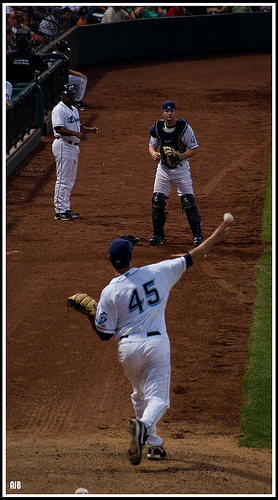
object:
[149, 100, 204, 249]
catcher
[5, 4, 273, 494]
field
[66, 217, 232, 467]
baseball player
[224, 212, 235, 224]
ball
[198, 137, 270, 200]
marks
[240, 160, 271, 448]
grass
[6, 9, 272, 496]
baseball feild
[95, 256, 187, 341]
baseball jersey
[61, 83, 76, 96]
helmet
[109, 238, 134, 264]
baseball hat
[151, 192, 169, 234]
shin guard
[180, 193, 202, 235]
shin guard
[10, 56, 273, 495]
ground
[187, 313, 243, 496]
dirt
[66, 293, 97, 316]
glove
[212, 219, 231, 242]
hand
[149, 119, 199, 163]
gear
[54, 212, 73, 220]
athletic shoe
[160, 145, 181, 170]
baseball glove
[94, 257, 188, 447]
uniform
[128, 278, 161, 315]
45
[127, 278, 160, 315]
print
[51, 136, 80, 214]
white pants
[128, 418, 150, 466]
shoe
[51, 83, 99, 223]
baseball player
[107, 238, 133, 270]
head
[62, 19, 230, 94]
wall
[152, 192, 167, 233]
guard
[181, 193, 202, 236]
guard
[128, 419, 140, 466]
cleat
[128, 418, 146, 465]
foot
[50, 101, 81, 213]
uniform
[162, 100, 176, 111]
cap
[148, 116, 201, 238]
uniform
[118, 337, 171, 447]
pants